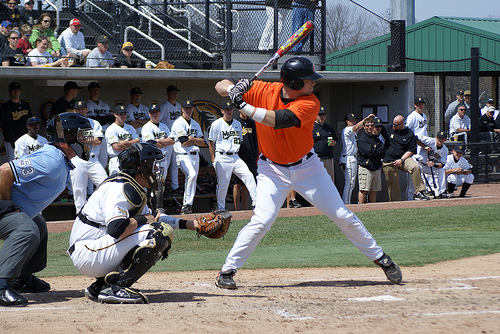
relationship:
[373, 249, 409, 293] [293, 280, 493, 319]
foot planted on ground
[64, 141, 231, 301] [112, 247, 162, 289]
person wearing shin guards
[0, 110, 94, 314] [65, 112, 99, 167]
man wears face protection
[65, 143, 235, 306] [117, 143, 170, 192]
person wears helmet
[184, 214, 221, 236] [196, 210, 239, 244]
hand has mitt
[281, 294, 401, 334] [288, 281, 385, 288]
dirt has shadow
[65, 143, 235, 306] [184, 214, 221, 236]
person has hand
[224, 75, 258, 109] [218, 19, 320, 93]
hands hold bat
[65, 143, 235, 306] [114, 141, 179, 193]
person has helmet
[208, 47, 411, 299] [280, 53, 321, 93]
man has helmet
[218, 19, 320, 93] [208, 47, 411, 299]
bat held by man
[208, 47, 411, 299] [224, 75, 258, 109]
man wears gloves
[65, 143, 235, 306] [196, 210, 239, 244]
person wears mitt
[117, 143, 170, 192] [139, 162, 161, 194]
helmet on face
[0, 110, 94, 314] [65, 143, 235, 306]
umpire behind person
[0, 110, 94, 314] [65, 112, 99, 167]
umpire has face guard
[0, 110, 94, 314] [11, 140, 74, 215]
umpire wears blue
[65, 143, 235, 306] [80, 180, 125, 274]
person wears white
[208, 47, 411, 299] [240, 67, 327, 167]
batter wears orange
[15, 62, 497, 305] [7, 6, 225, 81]
baseball field has bleachers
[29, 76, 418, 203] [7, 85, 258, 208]
dugout has team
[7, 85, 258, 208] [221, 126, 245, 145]
team has logo